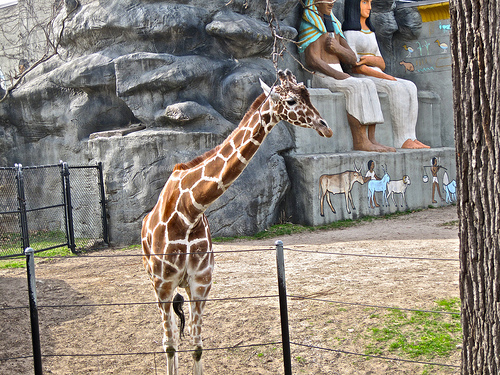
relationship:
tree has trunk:
[441, 3, 485, 362] [440, 8, 497, 326]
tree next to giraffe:
[441, 3, 485, 362] [165, 107, 272, 220]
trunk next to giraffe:
[440, 8, 497, 326] [165, 107, 272, 220]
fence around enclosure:
[0, 161, 462, 373] [2, 0, 498, 370]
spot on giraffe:
[216, 155, 246, 180] [114, 61, 336, 361]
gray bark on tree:
[467, 129, 495, 303] [443, 0, 490, 369]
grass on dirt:
[338, 255, 450, 373] [0, 245, 456, 368]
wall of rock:
[0, 1, 303, 248] [207, 13, 297, 66]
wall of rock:
[0, 1, 303, 248] [106, 46, 219, 126]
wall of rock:
[0, 1, 303, 248] [10, 52, 126, 134]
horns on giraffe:
[271, 63, 293, 85] [136, 67, 341, 373]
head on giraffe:
[273, 64, 334, 139] [136, 67, 341, 373]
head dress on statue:
[293, 0, 348, 52] [300, 0, 397, 152]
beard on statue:
[324, 15, 336, 33] [300, 0, 397, 152]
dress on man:
[294, 4, 344, 54] [292, 0, 352, 92]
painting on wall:
[325, 166, 457, 214] [314, 156, 461, 221]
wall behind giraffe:
[314, 156, 461, 221] [127, 54, 332, 374]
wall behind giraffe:
[0, 1, 303, 248] [129, 58, 309, 373]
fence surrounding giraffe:
[0, 161, 462, 373] [127, 54, 332, 374]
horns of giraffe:
[271, 63, 293, 85] [80, 37, 309, 307]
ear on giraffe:
[251, 78, 275, 101] [97, 52, 374, 373]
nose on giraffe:
[309, 110, 339, 145] [99, 62, 317, 372]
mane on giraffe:
[214, 100, 267, 139] [96, 57, 356, 294]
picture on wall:
[315, 158, 413, 220] [291, 147, 435, 228]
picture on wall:
[315, 158, 450, 221] [291, 147, 435, 228]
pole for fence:
[228, 226, 327, 361] [26, 203, 403, 360]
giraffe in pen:
[136, 67, 341, 373] [3, 2, 496, 372]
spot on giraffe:
[199, 154, 233, 182] [136, 67, 341, 373]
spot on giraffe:
[199, 154, 233, 182] [97, 52, 374, 373]